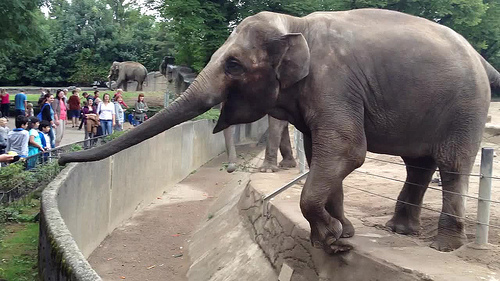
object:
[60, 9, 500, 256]
elephant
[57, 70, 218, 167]
trunk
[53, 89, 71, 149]
lady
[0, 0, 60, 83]
tree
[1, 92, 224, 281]
grass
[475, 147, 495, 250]
pole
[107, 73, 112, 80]
tusk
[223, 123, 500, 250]
fence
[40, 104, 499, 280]
pen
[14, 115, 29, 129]
hair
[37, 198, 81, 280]
weed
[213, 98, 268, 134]
mouth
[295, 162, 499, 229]
wire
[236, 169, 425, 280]
stone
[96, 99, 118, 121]
shirt